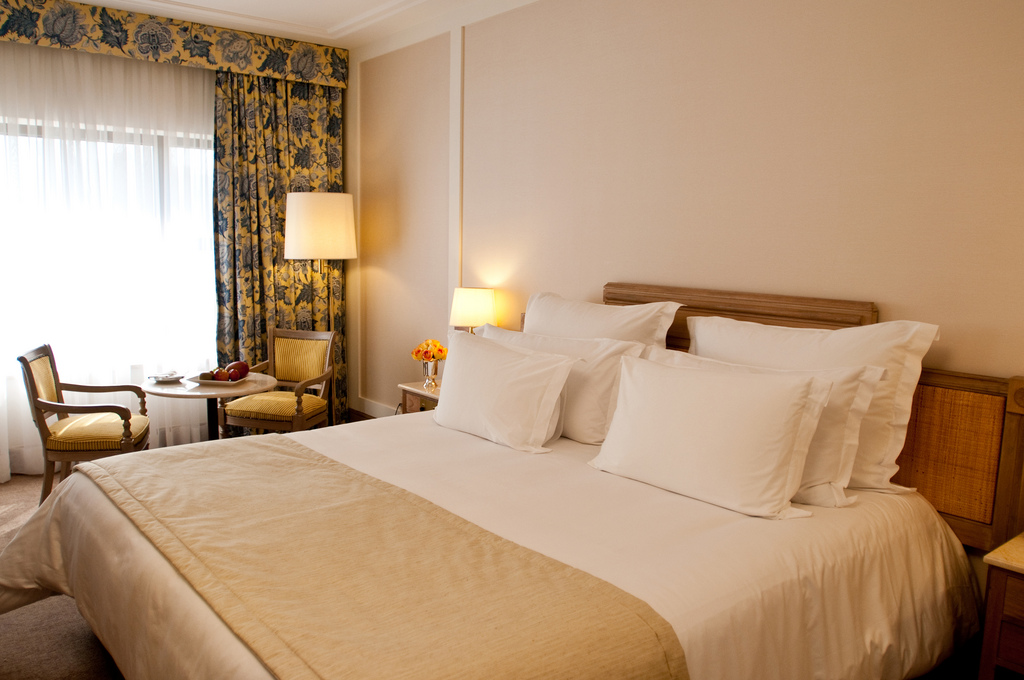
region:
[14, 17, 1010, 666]
large bed next to seating area in hotel room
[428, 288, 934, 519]
pillows propped up with smallest ones in front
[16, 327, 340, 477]
wooden chairs next to a small round table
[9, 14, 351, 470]
boldly-patterned draperies in front of sheer curtains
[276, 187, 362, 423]
lit standing lamp in corner of room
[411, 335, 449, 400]
small arrangement of orange flowers on top of night stand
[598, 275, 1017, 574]
wooden headboard composed of different panels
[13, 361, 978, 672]
brown blanket at foot of white bed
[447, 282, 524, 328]
drum-shaped shade glowing with light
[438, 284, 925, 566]
six pillows are on the bed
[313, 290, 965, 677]
white sheets and pillow cases are on the bed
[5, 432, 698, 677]
a beige coverlet turned down on the bed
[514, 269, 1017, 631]
the king size bed has a wooden headboard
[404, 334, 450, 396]
a vase has colorful flowers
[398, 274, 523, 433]
a lamp is on the bedside table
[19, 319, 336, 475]
a table and chairs are near the window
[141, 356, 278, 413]
objects are on the table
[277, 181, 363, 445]
a floor lamp is in the room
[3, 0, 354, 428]
the window has a valance and curtains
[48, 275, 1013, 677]
hotel room bed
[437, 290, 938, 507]
six white pillows on the bed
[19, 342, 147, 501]
wooden chair with a yellow seat cushion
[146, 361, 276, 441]
small round table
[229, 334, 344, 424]
wooden chair with yellow cushions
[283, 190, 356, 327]
floor lamp in the corner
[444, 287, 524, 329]
small lamp next to bed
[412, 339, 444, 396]
small flower arrangement on night stand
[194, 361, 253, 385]
plate of fruit on table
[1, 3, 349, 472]
large window in the hotel room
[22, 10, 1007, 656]
A clean hotelm room scence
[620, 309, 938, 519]
Three pillows stacked up behind another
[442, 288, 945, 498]
Six pillows leaving against the headboard.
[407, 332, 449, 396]
Flowers on the night stand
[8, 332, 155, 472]
One chair with beige upholstery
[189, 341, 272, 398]
A table with fruit on it.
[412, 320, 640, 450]
white pillows on bed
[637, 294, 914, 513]
white pillows on bed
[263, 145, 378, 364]
floor lamp in the corner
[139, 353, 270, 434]
a small round table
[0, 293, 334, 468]
a pair of chairs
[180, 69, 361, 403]
a yellow print curtain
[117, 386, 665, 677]
brown blanket on bed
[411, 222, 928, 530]
a set of pillows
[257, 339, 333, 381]
yellow back of chair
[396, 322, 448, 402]
flowers on the stand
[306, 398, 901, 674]
white cover on bed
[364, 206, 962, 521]
pillows on the bed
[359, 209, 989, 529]
white pillows on the bed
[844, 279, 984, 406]
corner of the pillow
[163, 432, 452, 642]
tan sheet on the bed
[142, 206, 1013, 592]
pillows on the white sheet